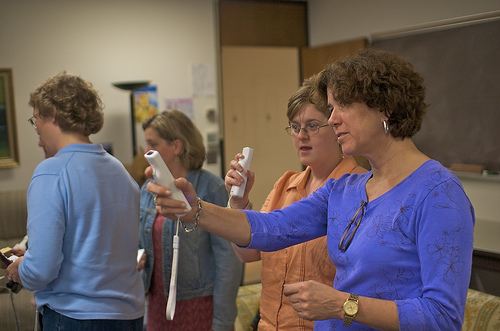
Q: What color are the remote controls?
A: White.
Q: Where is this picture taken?
A: Inside of a room in a building.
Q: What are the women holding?
A: Video game controllers.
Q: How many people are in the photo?
A: Four.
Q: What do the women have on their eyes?
A: Glasses.